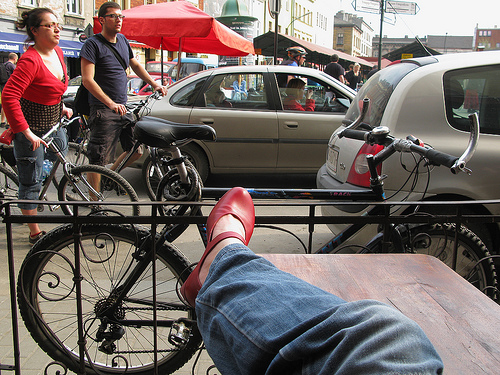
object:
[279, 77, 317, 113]
woman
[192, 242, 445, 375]
leg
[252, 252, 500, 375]
wood table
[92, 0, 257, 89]
umbrella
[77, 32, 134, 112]
shirt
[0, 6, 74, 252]
woman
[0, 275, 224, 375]
sidewalk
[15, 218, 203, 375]
tire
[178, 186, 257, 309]
shoe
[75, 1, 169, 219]
man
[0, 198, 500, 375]
fence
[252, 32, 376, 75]
black canopy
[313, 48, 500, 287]
car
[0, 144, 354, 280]
street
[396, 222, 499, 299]
tread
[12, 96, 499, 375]
bicycle